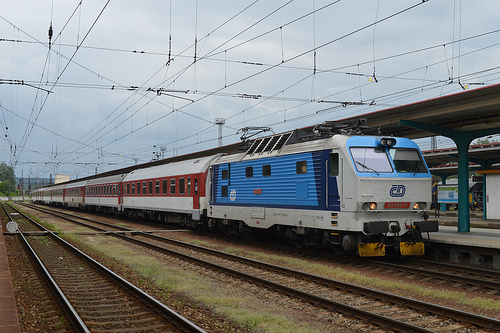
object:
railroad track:
[1, 201, 213, 331]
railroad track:
[375, 249, 499, 294]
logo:
[387, 186, 411, 199]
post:
[453, 129, 471, 232]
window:
[176, 177, 185, 194]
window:
[169, 177, 176, 192]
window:
[155, 177, 160, 193]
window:
[141, 180, 146, 194]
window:
[128, 182, 136, 194]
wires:
[0, 37, 497, 86]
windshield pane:
[390, 147, 427, 176]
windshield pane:
[349, 146, 392, 172]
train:
[27, 131, 439, 261]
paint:
[210, 152, 335, 210]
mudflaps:
[357, 244, 386, 256]